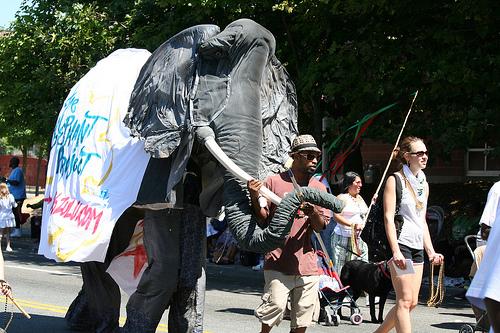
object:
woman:
[329, 171, 383, 307]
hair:
[331, 171, 360, 196]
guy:
[246, 134, 331, 333]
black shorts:
[385, 241, 424, 263]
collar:
[376, 261, 391, 279]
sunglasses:
[300, 150, 321, 163]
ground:
[0, 181, 500, 333]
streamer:
[313, 91, 418, 184]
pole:
[359, 91, 420, 231]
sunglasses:
[409, 150, 428, 157]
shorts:
[253, 269, 321, 328]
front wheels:
[325, 313, 363, 326]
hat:
[287, 134, 322, 157]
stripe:
[291, 143, 317, 153]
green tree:
[0, 0, 500, 163]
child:
[0, 181, 19, 252]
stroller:
[309, 229, 364, 326]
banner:
[38, 47, 154, 298]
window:
[464, 147, 500, 177]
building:
[312, 112, 500, 185]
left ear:
[261, 54, 301, 184]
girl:
[359, 135, 447, 333]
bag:
[359, 173, 405, 252]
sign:
[39, 80, 124, 263]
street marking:
[3, 272, 204, 333]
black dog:
[337, 259, 392, 324]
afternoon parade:
[0, 0, 500, 333]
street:
[0, 197, 500, 333]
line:
[0, 292, 67, 315]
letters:
[40, 90, 109, 234]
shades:
[410, 140, 428, 153]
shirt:
[258, 173, 332, 275]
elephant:
[38, 19, 346, 333]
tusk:
[201, 136, 281, 206]